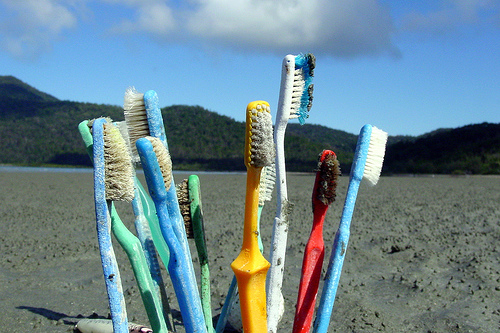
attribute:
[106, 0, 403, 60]
cloud — small, low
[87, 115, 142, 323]
toothbrush — light blue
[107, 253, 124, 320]
speckles — white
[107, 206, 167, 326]
toothbrush handle — light blue-green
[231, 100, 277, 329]
toothbrush — yellow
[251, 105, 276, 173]
bristles — gray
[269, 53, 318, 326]
toothbrush — white, tall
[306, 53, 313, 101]
sand — wet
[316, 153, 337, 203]
bristles — dark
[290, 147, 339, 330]
toothbrush — red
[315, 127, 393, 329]
toothbrush — light blue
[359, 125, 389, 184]
bristles — white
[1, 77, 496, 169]
hill — forested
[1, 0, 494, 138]
sky — blue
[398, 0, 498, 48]
clouds — small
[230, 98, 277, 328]
tooth brush — orange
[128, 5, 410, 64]
cloud — gray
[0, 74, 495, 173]
mountain range — small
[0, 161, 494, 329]
area — sand covered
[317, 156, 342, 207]
bristles — dirty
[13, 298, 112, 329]
shadow — dark 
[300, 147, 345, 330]
toothbrush — dirty , red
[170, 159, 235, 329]
toothbrush — shortest 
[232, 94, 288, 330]
toothbrush — dirty , yellow 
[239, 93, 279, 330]
toothbrush — yellow 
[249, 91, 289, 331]
toothbrush — yellow 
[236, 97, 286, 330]
toothbrush — yellow , used 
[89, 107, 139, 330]
toothbrush — used , blue 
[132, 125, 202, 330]
toothbrush — blue , used 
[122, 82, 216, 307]
toothbrush — used , blue 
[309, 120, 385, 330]
toothbrush — blue , used  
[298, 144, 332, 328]
toothbrush — used  , red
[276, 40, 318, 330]
toothbrush — used , white 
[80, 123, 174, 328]
toothbrush — used , green 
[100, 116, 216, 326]
toothbrush — green , used  